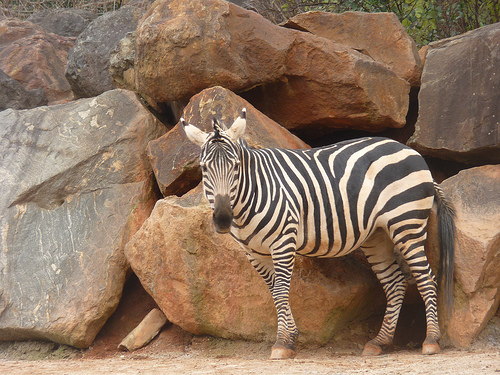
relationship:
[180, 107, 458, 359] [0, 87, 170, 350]
zebra next to rock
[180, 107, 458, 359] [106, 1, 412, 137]
zebra next to rock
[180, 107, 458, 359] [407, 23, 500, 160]
zebra next to rock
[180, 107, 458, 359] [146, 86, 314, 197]
zebra next to rock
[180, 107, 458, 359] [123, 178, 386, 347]
zebra next to rock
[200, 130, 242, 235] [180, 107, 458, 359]
head of zebra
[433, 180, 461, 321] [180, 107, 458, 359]
tail of zebra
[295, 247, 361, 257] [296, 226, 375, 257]
edge of tummy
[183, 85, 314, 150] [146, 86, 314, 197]
part of rock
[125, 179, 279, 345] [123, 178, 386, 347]
part of rock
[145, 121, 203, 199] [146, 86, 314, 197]
part of rock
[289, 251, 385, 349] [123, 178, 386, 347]
part of rock